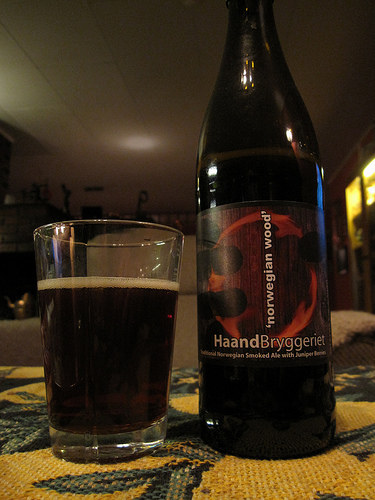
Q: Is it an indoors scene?
A: Yes, it is indoors.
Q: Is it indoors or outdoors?
A: It is indoors.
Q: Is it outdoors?
A: No, it is indoors.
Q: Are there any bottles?
A: Yes, there is a bottle.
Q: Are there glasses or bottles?
A: Yes, there is a bottle.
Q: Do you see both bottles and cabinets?
A: No, there is a bottle but no cabinets.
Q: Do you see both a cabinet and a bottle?
A: No, there is a bottle but no cabinets.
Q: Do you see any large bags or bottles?
A: Yes, there is a large bottle.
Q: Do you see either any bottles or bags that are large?
A: Yes, the bottle is large.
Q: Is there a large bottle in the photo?
A: Yes, there is a large bottle.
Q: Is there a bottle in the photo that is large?
A: Yes, there is a bottle that is large.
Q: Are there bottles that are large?
A: Yes, there is a bottle that is large.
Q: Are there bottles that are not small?
A: Yes, there is a large bottle.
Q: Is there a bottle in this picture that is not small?
A: Yes, there is a large bottle.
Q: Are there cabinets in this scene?
A: No, there are no cabinets.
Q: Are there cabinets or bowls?
A: No, there are no cabinets or bowls.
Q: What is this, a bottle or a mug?
A: This is a bottle.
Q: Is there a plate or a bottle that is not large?
A: No, there is a bottle but it is large.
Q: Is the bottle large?
A: Yes, the bottle is large.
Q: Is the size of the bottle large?
A: Yes, the bottle is large.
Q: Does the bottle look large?
A: Yes, the bottle is large.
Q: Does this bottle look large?
A: Yes, the bottle is large.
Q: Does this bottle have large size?
A: Yes, the bottle is large.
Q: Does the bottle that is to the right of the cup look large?
A: Yes, the bottle is large.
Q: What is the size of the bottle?
A: The bottle is large.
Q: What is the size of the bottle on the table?
A: The bottle is large.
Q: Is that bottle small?
A: No, the bottle is large.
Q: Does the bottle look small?
A: No, the bottle is large.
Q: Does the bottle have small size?
A: No, the bottle is large.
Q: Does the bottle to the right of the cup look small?
A: No, the bottle is large.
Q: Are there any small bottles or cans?
A: No, there is a bottle but it is large.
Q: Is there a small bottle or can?
A: No, there is a bottle but it is large.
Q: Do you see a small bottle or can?
A: No, there is a bottle but it is large.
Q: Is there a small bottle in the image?
A: No, there is a bottle but it is large.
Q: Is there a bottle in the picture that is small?
A: No, there is a bottle but it is large.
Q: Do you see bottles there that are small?
A: No, there is a bottle but it is large.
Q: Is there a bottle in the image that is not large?
A: No, there is a bottle but it is large.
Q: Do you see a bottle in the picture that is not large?
A: No, there is a bottle but it is large.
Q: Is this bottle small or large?
A: The bottle is large.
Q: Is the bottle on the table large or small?
A: The bottle is large.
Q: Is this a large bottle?
A: Yes, this is a large bottle.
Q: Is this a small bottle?
A: No, this is a large bottle.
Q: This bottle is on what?
A: The bottle is on the table.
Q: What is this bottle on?
A: The bottle is on the table.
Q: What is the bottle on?
A: The bottle is on the table.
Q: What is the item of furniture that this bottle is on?
A: The piece of furniture is a table.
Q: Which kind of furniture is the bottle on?
A: The bottle is on the table.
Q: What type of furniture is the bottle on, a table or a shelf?
A: The bottle is on a table.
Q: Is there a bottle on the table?
A: Yes, there is a bottle on the table.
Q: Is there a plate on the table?
A: No, there is a bottle on the table.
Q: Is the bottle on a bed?
A: No, the bottle is on the table.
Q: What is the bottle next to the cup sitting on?
A: The bottle is sitting on the table.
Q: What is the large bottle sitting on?
A: The bottle is sitting on the table.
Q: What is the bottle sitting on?
A: The bottle is sitting on the table.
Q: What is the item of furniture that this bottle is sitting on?
A: The piece of furniture is a table.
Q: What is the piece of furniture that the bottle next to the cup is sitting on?
A: The piece of furniture is a table.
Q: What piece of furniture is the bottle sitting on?
A: The bottle is sitting on the table.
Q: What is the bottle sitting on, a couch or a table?
A: The bottle is sitting on a table.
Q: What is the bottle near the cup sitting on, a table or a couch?
A: The bottle is sitting on a table.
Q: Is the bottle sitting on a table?
A: Yes, the bottle is sitting on a table.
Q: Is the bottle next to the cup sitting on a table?
A: Yes, the bottle is sitting on a table.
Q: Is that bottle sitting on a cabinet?
A: No, the bottle is sitting on a table.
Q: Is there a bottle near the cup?
A: Yes, there is a bottle near the cup.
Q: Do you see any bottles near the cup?
A: Yes, there is a bottle near the cup.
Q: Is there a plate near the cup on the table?
A: No, there is a bottle near the cup.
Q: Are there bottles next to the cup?
A: Yes, there is a bottle next to the cup.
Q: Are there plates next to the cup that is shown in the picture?
A: No, there is a bottle next to the cup.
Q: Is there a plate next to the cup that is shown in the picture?
A: No, there is a bottle next to the cup.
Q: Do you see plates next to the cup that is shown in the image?
A: No, there is a bottle next to the cup.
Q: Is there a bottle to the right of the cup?
A: Yes, there is a bottle to the right of the cup.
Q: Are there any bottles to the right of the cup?
A: Yes, there is a bottle to the right of the cup.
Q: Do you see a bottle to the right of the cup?
A: Yes, there is a bottle to the right of the cup.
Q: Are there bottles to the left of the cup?
A: No, the bottle is to the right of the cup.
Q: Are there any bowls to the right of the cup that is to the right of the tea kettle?
A: No, there is a bottle to the right of the cup.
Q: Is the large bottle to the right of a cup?
A: Yes, the bottle is to the right of a cup.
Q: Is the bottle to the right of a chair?
A: No, the bottle is to the right of a cup.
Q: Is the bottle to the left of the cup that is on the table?
A: No, the bottle is to the right of the cup.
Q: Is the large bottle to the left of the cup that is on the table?
A: No, the bottle is to the right of the cup.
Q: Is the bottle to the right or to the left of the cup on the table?
A: The bottle is to the right of the cup.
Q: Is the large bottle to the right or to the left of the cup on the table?
A: The bottle is to the right of the cup.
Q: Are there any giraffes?
A: No, there are no giraffes.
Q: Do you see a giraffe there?
A: No, there are no giraffes.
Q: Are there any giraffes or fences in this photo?
A: No, there are no giraffes or fences.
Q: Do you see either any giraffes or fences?
A: No, there are no giraffes or fences.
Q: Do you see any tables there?
A: Yes, there is a table.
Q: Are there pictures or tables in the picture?
A: Yes, there is a table.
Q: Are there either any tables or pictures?
A: Yes, there is a table.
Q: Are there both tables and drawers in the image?
A: No, there is a table but no drawers.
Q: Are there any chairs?
A: No, there are no chairs.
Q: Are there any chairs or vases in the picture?
A: No, there are no chairs or vases.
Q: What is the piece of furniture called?
A: The piece of furniture is a table.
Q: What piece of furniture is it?
A: The piece of furniture is a table.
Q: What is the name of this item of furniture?
A: This is a table.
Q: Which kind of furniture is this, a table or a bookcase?
A: This is a table.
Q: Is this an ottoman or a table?
A: This is a table.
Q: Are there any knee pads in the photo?
A: No, there are no knee pads.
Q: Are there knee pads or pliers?
A: No, there are no knee pads or pliers.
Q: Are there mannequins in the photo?
A: No, there are no mannequins.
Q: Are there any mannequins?
A: No, there are no mannequins.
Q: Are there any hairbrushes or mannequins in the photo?
A: No, there are no mannequins or hairbrushes.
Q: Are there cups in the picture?
A: Yes, there is a cup.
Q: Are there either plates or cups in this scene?
A: Yes, there is a cup.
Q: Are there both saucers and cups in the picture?
A: No, there is a cup but no saucers.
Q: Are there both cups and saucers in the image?
A: No, there is a cup but no saucers.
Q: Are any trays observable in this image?
A: No, there are no trays.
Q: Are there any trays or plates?
A: No, there are no trays or plates.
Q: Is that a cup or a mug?
A: That is a cup.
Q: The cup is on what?
A: The cup is on the table.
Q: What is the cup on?
A: The cup is on the table.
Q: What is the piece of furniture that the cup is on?
A: The piece of furniture is a table.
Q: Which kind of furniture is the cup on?
A: The cup is on the table.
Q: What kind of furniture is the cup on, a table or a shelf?
A: The cup is on a table.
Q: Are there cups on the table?
A: Yes, there is a cup on the table.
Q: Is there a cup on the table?
A: Yes, there is a cup on the table.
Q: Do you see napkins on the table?
A: No, there is a cup on the table.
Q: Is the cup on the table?
A: Yes, the cup is on the table.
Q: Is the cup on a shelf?
A: No, the cup is on the table.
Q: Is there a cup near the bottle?
A: Yes, there is a cup near the bottle.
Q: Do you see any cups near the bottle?
A: Yes, there is a cup near the bottle.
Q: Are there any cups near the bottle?
A: Yes, there is a cup near the bottle.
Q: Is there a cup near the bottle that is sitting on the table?
A: Yes, there is a cup near the bottle.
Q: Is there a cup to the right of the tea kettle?
A: Yes, there is a cup to the right of the tea kettle.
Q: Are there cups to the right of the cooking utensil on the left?
A: Yes, there is a cup to the right of the tea kettle.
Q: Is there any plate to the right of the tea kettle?
A: No, there is a cup to the right of the tea kettle.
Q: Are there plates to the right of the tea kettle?
A: No, there is a cup to the right of the tea kettle.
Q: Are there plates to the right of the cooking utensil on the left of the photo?
A: No, there is a cup to the right of the tea kettle.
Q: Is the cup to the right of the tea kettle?
A: Yes, the cup is to the right of the tea kettle.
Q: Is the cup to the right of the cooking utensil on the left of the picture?
A: Yes, the cup is to the right of the tea kettle.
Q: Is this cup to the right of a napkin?
A: No, the cup is to the right of the tea kettle.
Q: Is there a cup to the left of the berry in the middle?
A: Yes, there is a cup to the left of the berry.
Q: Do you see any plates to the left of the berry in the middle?
A: No, there is a cup to the left of the berry.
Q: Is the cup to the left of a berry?
A: Yes, the cup is to the left of a berry.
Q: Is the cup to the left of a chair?
A: No, the cup is to the left of a berry.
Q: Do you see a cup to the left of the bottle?
A: Yes, there is a cup to the left of the bottle.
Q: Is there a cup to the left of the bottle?
A: Yes, there is a cup to the left of the bottle.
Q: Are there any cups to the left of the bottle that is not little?
A: Yes, there is a cup to the left of the bottle.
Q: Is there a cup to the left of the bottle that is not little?
A: Yes, there is a cup to the left of the bottle.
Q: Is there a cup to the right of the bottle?
A: No, the cup is to the left of the bottle.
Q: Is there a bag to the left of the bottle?
A: No, there is a cup to the left of the bottle.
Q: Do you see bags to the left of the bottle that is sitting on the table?
A: No, there is a cup to the left of the bottle.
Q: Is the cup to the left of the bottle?
A: Yes, the cup is to the left of the bottle.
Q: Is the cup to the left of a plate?
A: No, the cup is to the left of the bottle.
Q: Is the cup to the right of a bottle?
A: No, the cup is to the left of a bottle.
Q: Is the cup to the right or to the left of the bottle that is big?
A: The cup is to the left of the bottle.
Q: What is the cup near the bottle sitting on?
A: The cup is sitting on the table.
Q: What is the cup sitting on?
A: The cup is sitting on the table.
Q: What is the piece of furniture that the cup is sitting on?
A: The piece of furniture is a table.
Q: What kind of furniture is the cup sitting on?
A: The cup is sitting on the table.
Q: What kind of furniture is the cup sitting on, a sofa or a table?
A: The cup is sitting on a table.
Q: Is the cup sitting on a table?
A: Yes, the cup is sitting on a table.